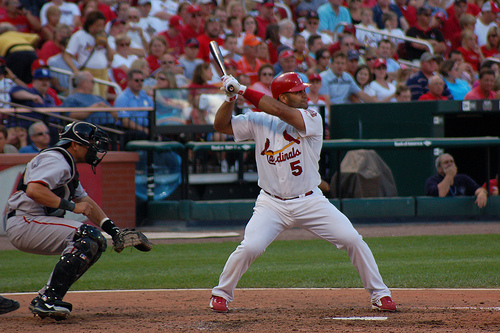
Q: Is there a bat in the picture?
A: Yes, there is a bat.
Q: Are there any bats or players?
A: Yes, there is a bat.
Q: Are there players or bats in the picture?
A: Yes, there is a bat.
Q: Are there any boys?
A: No, there are no boys.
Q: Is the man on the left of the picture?
A: Yes, the man is on the left of the image.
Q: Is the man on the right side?
A: No, the man is on the left of the image.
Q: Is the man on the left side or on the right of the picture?
A: The man is on the left of the image.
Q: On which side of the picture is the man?
A: The man is on the left of the image.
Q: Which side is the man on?
A: The man is on the left of the image.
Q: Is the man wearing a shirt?
A: Yes, the man is wearing a shirt.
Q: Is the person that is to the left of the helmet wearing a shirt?
A: Yes, the man is wearing a shirt.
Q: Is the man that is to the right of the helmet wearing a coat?
A: No, the man is wearing a shirt.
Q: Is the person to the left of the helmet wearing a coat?
A: No, the man is wearing a shirt.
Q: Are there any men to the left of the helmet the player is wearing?
A: Yes, there is a man to the left of the helmet.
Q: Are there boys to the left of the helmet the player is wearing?
A: No, there is a man to the left of the helmet.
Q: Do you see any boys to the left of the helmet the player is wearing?
A: No, there is a man to the left of the helmet.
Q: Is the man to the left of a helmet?
A: Yes, the man is to the left of a helmet.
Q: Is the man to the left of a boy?
A: No, the man is to the left of a helmet.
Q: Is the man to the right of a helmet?
A: No, the man is to the left of a helmet.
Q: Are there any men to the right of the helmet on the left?
A: Yes, there is a man to the right of the helmet.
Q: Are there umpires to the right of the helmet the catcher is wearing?
A: No, there is a man to the right of the helmet.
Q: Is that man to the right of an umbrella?
A: No, the man is to the right of the helmet.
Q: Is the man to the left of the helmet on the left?
A: No, the man is to the right of the helmet.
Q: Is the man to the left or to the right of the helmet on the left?
A: The man is to the right of the helmet.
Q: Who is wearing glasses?
A: The man is wearing glasses.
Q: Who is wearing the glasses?
A: The man is wearing glasses.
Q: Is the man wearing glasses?
A: Yes, the man is wearing glasses.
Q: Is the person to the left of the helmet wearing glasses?
A: Yes, the man is wearing glasses.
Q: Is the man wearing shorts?
A: No, the man is wearing glasses.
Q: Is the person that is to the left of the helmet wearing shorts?
A: No, the man is wearing glasses.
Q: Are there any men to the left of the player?
A: Yes, there is a man to the left of the player.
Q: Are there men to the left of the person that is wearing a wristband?
A: Yes, there is a man to the left of the player.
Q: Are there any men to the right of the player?
A: No, the man is to the left of the player.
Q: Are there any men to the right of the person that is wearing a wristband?
A: No, the man is to the left of the player.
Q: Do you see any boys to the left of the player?
A: No, there is a man to the left of the player.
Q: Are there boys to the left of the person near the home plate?
A: No, there is a man to the left of the player.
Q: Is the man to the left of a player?
A: Yes, the man is to the left of a player.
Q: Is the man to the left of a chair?
A: No, the man is to the left of a player.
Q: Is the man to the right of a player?
A: No, the man is to the left of a player.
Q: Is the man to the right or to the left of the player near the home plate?
A: The man is to the left of the player.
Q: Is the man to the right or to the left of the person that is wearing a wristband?
A: The man is to the left of the player.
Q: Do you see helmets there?
A: Yes, there is a helmet.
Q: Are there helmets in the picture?
A: Yes, there is a helmet.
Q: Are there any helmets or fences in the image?
A: Yes, there is a helmet.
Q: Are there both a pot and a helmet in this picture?
A: No, there is a helmet but no pots.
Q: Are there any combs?
A: No, there are no combs.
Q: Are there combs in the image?
A: No, there are no combs.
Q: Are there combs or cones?
A: No, there are no combs or cones.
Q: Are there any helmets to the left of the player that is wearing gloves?
A: Yes, there is a helmet to the left of the player.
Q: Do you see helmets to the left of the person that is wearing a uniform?
A: Yes, there is a helmet to the left of the player.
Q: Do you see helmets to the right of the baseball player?
A: No, the helmet is to the left of the player.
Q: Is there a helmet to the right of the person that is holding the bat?
A: No, the helmet is to the left of the player.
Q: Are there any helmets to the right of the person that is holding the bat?
A: No, the helmet is to the left of the player.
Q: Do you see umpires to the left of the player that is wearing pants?
A: No, there is a helmet to the left of the player.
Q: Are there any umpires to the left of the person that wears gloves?
A: No, there is a helmet to the left of the player.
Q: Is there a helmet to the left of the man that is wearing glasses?
A: Yes, there is a helmet to the left of the man.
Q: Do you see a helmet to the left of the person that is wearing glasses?
A: Yes, there is a helmet to the left of the man.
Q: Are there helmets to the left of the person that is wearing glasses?
A: Yes, there is a helmet to the left of the man.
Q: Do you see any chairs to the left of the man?
A: No, there is a helmet to the left of the man.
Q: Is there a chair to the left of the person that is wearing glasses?
A: No, there is a helmet to the left of the man.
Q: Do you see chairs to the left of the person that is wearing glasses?
A: No, there is a helmet to the left of the man.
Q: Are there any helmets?
A: Yes, there is a helmet.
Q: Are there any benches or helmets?
A: Yes, there is a helmet.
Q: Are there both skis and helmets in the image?
A: No, there is a helmet but no skis.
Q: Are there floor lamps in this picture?
A: No, there are no floor lamps.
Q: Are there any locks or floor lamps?
A: No, there are no floor lamps or locks.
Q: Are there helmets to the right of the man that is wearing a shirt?
A: Yes, there is a helmet to the right of the man.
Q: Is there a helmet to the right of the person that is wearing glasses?
A: Yes, there is a helmet to the right of the man.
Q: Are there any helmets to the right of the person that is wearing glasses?
A: Yes, there is a helmet to the right of the man.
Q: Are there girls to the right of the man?
A: No, there is a helmet to the right of the man.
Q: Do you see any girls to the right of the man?
A: No, there is a helmet to the right of the man.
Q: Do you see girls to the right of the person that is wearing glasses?
A: No, there is a helmet to the right of the man.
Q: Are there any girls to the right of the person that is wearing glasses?
A: No, there is a helmet to the right of the man.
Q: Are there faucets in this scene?
A: No, there are no faucets.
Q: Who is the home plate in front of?
A: The home plate is in front of the catcher.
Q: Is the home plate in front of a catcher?
A: Yes, the home plate is in front of a catcher.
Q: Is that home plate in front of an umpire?
A: No, the home plate is in front of a catcher.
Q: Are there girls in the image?
A: No, there are no girls.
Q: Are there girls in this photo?
A: No, there are no girls.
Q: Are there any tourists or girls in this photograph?
A: No, there are no girls or tourists.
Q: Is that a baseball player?
A: Yes, that is a baseball player.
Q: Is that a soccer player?
A: No, that is a baseball player.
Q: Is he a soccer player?
A: No, that is a baseball player.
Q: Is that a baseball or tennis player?
A: That is a baseball player.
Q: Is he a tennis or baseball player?
A: That is a baseball player.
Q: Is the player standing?
A: Yes, the player is standing.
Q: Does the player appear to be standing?
A: Yes, the player is standing.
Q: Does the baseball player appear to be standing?
A: Yes, the player is standing.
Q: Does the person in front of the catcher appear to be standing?
A: Yes, the player is standing.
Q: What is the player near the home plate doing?
A: The player is standing.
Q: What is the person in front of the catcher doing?
A: The player is standing.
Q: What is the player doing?
A: The player is standing.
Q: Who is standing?
A: The player is standing.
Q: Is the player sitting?
A: No, the player is standing.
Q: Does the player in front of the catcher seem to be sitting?
A: No, the player is standing.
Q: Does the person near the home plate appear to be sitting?
A: No, the player is standing.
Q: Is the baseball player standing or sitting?
A: The player is standing.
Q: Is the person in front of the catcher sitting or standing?
A: The player is standing.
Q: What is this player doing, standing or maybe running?
A: The player is standing.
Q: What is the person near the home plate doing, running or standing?
A: The player is standing.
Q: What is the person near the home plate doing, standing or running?
A: The player is standing.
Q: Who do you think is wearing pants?
A: The player is wearing pants.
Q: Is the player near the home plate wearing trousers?
A: Yes, the player is wearing trousers.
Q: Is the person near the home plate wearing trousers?
A: Yes, the player is wearing trousers.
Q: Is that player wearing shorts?
A: No, the player is wearing trousers.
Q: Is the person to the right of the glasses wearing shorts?
A: No, the player is wearing trousers.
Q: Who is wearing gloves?
A: The player is wearing gloves.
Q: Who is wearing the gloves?
A: The player is wearing gloves.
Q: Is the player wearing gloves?
A: Yes, the player is wearing gloves.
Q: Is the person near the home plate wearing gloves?
A: Yes, the player is wearing gloves.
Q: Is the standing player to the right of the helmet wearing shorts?
A: No, the player is wearing gloves.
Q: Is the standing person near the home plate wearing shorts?
A: No, the player is wearing gloves.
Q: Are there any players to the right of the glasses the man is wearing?
A: Yes, there is a player to the right of the glasses.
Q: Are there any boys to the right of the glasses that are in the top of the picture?
A: No, there is a player to the right of the glasses.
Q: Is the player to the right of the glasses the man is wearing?
A: Yes, the player is to the right of the glasses.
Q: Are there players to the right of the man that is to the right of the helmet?
A: Yes, there is a player to the right of the man.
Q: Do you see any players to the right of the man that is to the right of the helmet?
A: Yes, there is a player to the right of the man.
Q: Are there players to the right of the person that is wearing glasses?
A: Yes, there is a player to the right of the man.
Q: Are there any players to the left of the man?
A: No, the player is to the right of the man.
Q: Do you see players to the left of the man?
A: No, the player is to the right of the man.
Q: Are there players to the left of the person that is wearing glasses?
A: No, the player is to the right of the man.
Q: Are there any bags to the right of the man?
A: No, there is a player to the right of the man.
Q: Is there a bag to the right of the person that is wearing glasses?
A: No, there is a player to the right of the man.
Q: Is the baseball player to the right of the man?
A: Yes, the player is to the right of the man.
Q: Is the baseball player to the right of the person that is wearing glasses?
A: Yes, the player is to the right of the man.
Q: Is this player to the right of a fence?
A: No, the player is to the right of the man.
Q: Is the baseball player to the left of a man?
A: No, the player is to the right of a man.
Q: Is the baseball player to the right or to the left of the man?
A: The player is to the right of the man.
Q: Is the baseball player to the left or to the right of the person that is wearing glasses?
A: The player is to the right of the man.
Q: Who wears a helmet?
A: The player wears a helmet.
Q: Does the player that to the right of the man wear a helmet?
A: Yes, the player wears a helmet.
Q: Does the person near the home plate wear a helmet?
A: Yes, the player wears a helmet.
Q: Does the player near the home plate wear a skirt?
A: No, the player wears a helmet.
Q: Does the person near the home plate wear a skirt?
A: No, the player wears a helmet.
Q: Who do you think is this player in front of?
A: The player is in front of the catcher.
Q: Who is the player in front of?
A: The player is in front of the catcher.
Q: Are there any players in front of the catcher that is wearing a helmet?
A: Yes, there is a player in front of the catcher.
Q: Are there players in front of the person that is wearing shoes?
A: Yes, there is a player in front of the catcher.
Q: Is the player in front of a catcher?
A: Yes, the player is in front of a catcher.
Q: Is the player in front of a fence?
A: No, the player is in front of a catcher.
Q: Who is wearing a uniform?
A: The player is wearing a uniform.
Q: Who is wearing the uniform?
A: The player is wearing a uniform.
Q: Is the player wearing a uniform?
A: Yes, the player is wearing a uniform.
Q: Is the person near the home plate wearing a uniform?
A: Yes, the player is wearing a uniform.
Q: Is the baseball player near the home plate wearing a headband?
A: No, the player is wearing a uniform.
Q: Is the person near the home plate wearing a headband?
A: No, the player is wearing a uniform.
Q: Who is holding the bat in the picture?
A: The player is holding the bat.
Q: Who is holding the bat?
A: The player is holding the bat.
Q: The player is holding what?
A: The player is holding the bat.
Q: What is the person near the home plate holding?
A: The player is holding the bat.